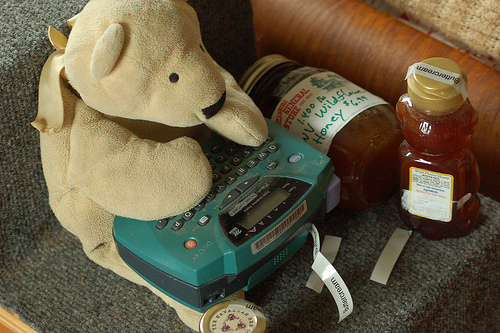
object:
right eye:
[168, 72, 180, 84]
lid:
[238, 53, 299, 95]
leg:
[90, 237, 244, 332]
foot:
[169, 301, 243, 333]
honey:
[395, 56, 482, 241]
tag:
[369, 225, 412, 286]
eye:
[168, 72, 180, 84]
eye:
[199, 44, 205, 53]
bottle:
[396, 57, 481, 242]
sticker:
[306, 224, 356, 324]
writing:
[329, 277, 349, 314]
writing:
[297, 87, 367, 144]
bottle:
[236, 53, 405, 209]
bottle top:
[197, 299, 265, 333]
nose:
[199, 90, 227, 120]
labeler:
[112, 116, 344, 315]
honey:
[238, 54, 403, 212]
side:
[252, 1, 499, 202]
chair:
[1, 1, 500, 333]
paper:
[306, 224, 355, 324]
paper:
[369, 228, 415, 286]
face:
[118, 6, 227, 128]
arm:
[64, 125, 209, 221]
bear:
[28, 0, 269, 332]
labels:
[305, 222, 356, 325]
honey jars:
[239, 50, 402, 210]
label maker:
[149, 130, 329, 305]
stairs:
[2, 0, 500, 333]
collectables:
[29, 0, 482, 330]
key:
[266, 144, 279, 154]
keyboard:
[146, 122, 281, 233]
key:
[234, 167, 247, 177]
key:
[225, 175, 237, 184]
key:
[220, 188, 241, 209]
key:
[171, 219, 184, 231]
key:
[205, 194, 216, 203]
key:
[225, 147, 237, 155]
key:
[256, 152, 268, 161]